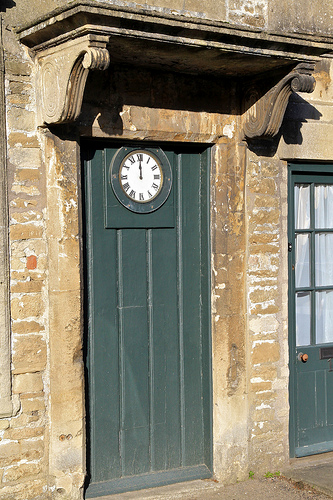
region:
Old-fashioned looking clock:
[102, 142, 176, 214]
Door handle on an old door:
[289, 347, 314, 368]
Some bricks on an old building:
[244, 270, 280, 395]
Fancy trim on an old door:
[15, 45, 120, 131]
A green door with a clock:
[41, 124, 247, 498]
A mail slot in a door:
[316, 341, 331, 365]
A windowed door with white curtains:
[269, 165, 330, 357]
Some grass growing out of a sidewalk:
[239, 460, 288, 489]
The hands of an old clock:
[132, 151, 148, 183]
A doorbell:
[275, 234, 301, 258]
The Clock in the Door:
[100, 127, 188, 243]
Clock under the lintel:
[14, 12, 283, 262]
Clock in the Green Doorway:
[64, 129, 222, 495]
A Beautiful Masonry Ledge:
[14, 8, 328, 242]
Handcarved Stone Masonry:
[21, 38, 114, 138]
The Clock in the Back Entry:
[21, 9, 269, 288]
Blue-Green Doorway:
[28, 3, 248, 442]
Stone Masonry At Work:
[19, 4, 218, 430]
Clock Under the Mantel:
[21, 8, 272, 301]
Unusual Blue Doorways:
[128, 121, 331, 359]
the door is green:
[283, 156, 330, 459]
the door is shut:
[283, 152, 330, 462]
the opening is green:
[75, 136, 220, 495]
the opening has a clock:
[81, 135, 215, 496]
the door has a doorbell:
[285, 238, 291, 251]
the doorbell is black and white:
[285, 238, 292, 251]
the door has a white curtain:
[291, 180, 329, 348]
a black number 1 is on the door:
[324, 354, 330, 373]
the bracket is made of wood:
[29, 28, 110, 131]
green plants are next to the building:
[244, 466, 284, 482]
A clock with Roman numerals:
[99, 146, 184, 224]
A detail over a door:
[24, 35, 119, 132]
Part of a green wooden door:
[111, 340, 196, 424]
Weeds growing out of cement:
[243, 457, 285, 493]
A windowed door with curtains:
[280, 157, 331, 346]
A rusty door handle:
[288, 346, 310, 370]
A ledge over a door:
[9, 6, 329, 147]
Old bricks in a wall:
[13, 161, 47, 381]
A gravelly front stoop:
[240, 484, 270, 496]